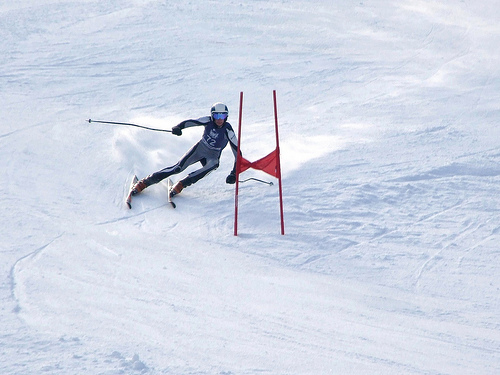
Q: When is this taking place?
A: Daytime.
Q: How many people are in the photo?
A: One.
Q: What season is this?
A: Winter.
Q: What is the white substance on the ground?
A: Snow.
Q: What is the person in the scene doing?
A: Skiing.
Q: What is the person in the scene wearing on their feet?
A: Skis.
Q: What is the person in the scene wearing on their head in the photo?
A: Helmet.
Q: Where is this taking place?
A: On a ski slope.